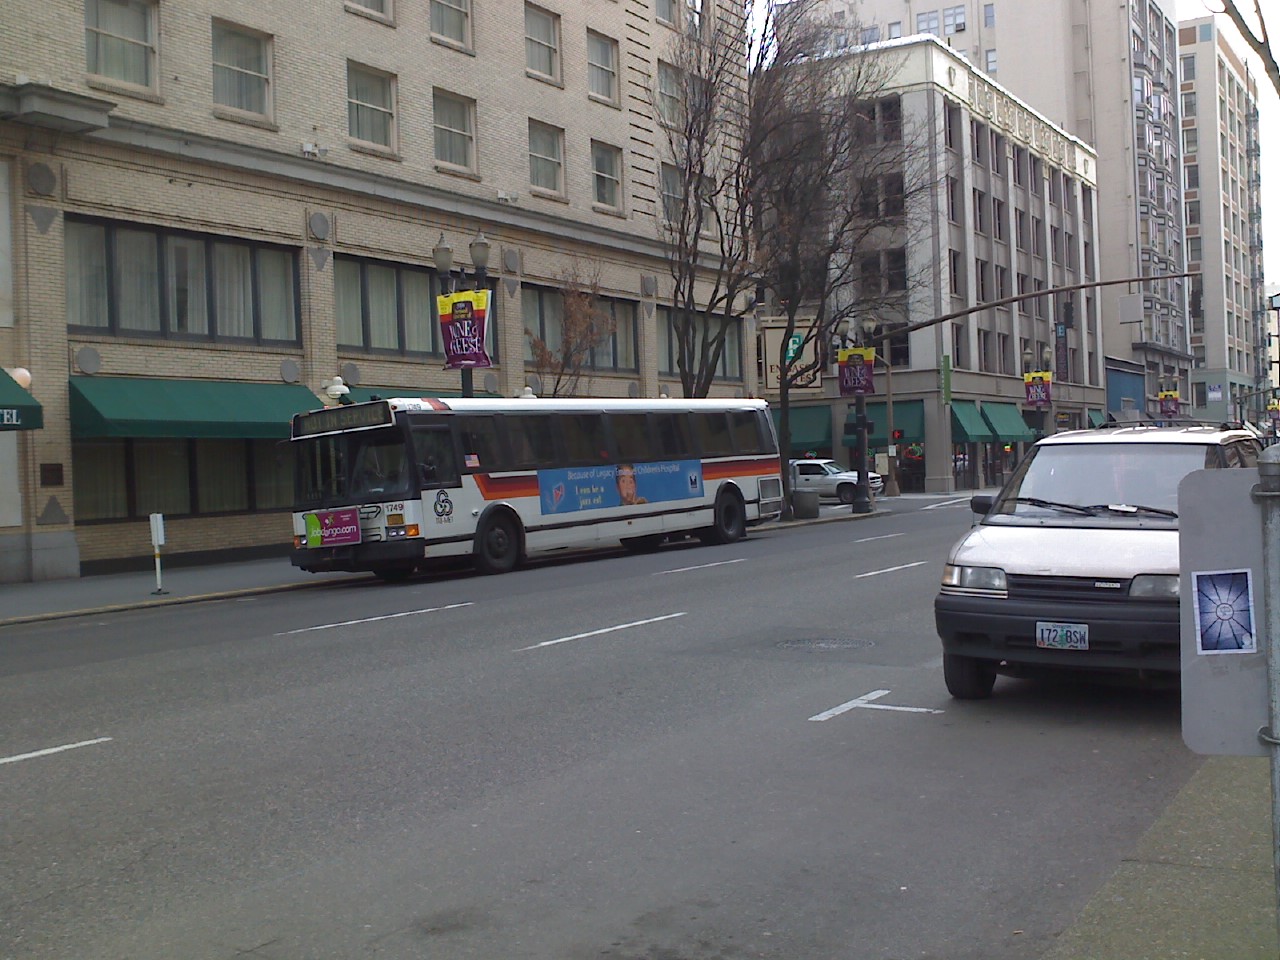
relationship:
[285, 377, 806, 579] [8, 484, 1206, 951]
bus parked on street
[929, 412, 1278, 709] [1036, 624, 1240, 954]
suv parked next to curb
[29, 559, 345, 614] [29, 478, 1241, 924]
curb next to street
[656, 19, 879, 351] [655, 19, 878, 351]
leaves have leaves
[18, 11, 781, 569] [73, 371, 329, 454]
building has awning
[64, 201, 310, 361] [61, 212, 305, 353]
windows have curtains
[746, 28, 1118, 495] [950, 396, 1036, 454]
building has awnings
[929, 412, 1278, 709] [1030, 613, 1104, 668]
suv has plate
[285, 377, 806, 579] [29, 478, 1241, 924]
bus in street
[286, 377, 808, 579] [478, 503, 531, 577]
bus has wheel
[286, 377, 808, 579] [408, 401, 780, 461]
bus has windows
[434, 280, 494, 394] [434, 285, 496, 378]
streetlight has banner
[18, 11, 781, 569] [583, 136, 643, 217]
building has window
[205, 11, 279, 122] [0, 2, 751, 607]
window on a building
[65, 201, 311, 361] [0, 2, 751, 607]
windows on a building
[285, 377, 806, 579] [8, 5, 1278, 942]
bus in city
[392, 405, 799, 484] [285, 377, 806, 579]
windows on bus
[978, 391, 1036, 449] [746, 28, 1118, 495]
awning on building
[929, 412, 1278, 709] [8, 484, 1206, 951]
suv parked in street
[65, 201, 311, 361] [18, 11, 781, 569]
windows on building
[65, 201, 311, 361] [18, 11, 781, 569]
windows attached to building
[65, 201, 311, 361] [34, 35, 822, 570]
windows attached to building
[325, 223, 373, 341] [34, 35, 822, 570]
window attached to building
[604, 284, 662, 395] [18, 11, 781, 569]
window attached to building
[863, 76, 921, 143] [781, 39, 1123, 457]
window attached to building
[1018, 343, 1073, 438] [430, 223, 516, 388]
banner attached to light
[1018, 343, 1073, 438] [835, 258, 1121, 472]
banner attached to light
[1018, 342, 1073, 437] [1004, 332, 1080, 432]
banner attached to light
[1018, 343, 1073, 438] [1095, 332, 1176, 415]
banner attached to light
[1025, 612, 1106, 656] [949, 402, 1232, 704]
plate attached to car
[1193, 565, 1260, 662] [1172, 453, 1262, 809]
sticker attached to sign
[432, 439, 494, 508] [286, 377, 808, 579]
flag attached to bus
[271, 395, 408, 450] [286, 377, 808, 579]
display attached to bus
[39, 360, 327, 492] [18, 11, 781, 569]
awning attached to building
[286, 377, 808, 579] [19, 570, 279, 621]
bus stopped sidwalk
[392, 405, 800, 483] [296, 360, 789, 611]
windows on bus